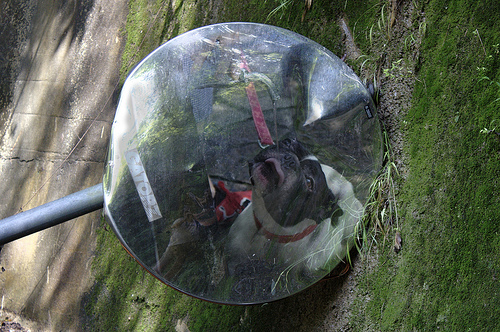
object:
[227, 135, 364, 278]
dog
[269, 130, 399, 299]
grass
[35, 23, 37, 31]
exist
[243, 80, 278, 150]
stripe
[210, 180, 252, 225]
shoe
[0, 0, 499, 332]
ground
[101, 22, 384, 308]
glass